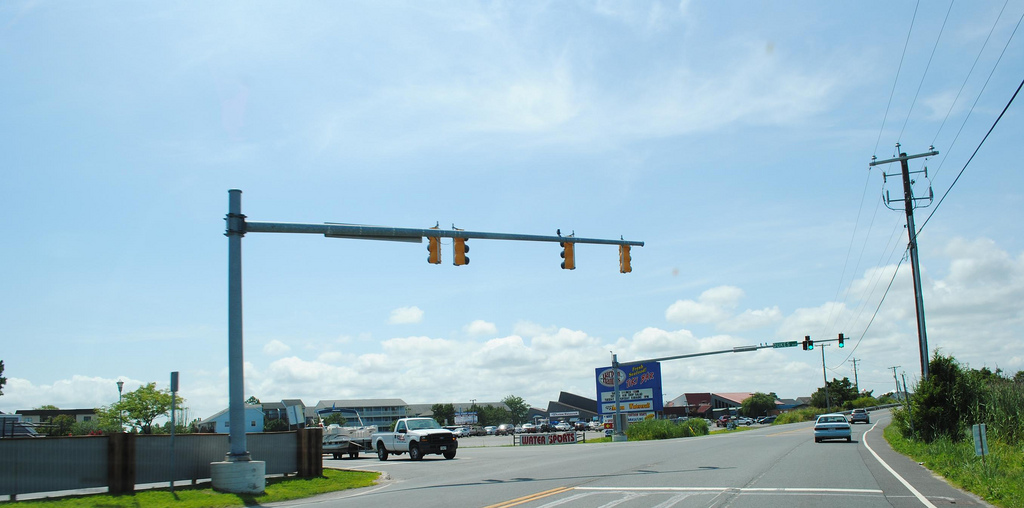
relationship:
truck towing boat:
[360, 410, 466, 469] [315, 428, 372, 454]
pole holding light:
[220, 182, 644, 459] [613, 242, 633, 275]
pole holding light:
[220, 182, 644, 459] [555, 229, 577, 269]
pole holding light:
[220, 182, 644, 459] [447, 233, 471, 268]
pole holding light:
[220, 182, 644, 459] [419, 222, 446, 266]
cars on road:
[818, 390, 871, 466] [617, 452, 825, 500]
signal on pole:
[432, 227, 638, 267] [224, 197, 264, 491]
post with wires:
[222, 204, 253, 457] [248, 1, 992, 364]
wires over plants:
[829, 0, 1007, 223] [905, 361, 1018, 504]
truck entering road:
[372, 405, 461, 460] [292, 407, 915, 503]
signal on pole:
[418, 214, 440, 264] [178, 175, 658, 474]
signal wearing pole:
[446, 229, 477, 268] [208, 173, 673, 459]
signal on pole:
[550, 229, 596, 279] [208, 173, 673, 459]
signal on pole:
[614, 234, 662, 306] [209, 188, 646, 491]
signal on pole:
[831, 314, 858, 351] [608, 318, 881, 435]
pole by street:
[607, 355, 623, 444] [283, 392, 1005, 503]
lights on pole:
[419, 225, 634, 273] [220, 182, 644, 459]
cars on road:
[808, 394, 876, 446] [283, 394, 990, 503]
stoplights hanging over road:
[423, 227, 450, 262] [278, 379, 1004, 501]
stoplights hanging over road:
[449, 232, 476, 267] [278, 379, 1004, 501]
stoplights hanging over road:
[555, 234, 582, 276] [278, 379, 1004, 501]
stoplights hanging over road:
[613, 243, 635, 276] [278, 379, 1004, 501]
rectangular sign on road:
[478, 419, 593, 458] [475, 397, 778, 508]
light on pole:
[619, 238, 633, 275] [223, 188, 649, 435]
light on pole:
[556, 238, 576, 269] [209, 188, 646, 491]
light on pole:
[425, 234, 445, 265] [209, 188, 646, 491]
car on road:
[474, 404, 522, 435] [472, 452, 524, 476]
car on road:
[494, 424, 516, 436] [463, 435, 582, 488]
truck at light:
[387, 441, 450, 470] [292, 186, 634, 275]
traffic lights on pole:
[394, 210, 682, 301] [169, 173, 336, 424]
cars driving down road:
[791, 411, 917, 461] [664, 428, 801, 493]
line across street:
[538, 465, 889, 502] [566, 424, 705, 498]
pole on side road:
[828, 161, 989, 460] [660, 441, 894, 504]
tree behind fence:
[91, 381, 174, 418] [89, 405, 165, 479]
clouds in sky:
[359, 363, 440, 381] [348, 340, 441, 362]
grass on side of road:
[258, 471, 311, 497] [357, 467, 455, 502]